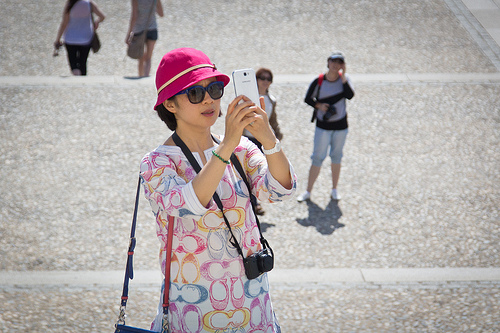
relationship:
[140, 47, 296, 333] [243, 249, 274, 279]
woman has camera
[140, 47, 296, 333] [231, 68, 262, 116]
woman has camera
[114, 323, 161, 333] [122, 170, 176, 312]
bag has strap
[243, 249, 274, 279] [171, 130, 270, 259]
camera has strap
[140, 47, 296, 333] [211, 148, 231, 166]
woman has bracelet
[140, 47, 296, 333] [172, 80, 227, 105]
woman has glasses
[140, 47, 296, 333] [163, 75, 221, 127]
woman has face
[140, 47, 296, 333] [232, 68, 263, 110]
woman has camera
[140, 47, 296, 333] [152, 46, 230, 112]
woman has hat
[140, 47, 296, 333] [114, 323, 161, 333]
woman has bag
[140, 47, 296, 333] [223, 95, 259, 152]
woman has hand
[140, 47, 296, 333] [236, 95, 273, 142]
woman has hand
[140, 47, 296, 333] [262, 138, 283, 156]
woman has watch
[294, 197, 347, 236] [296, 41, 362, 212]
shadow of person